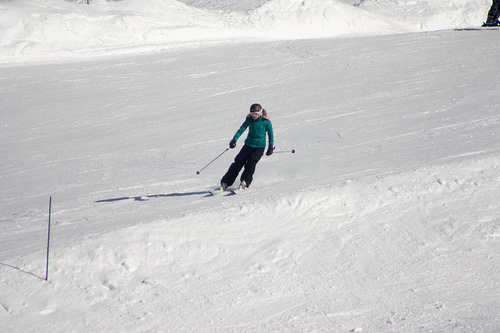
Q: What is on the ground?
A: Snow.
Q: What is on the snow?
A: Tracks.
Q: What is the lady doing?
A: Skiing.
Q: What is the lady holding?
A: Poles.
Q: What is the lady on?
A: Skis.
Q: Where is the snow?
A: On the hill.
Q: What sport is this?
A: Skiing.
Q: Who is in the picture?
A: A woman.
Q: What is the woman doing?
A: Skiing.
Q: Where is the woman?
A: At a ski slope.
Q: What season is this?
A: Winter.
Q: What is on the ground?
A: Snow.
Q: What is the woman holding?
A: Poles.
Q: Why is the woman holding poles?
A: Speed.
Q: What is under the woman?
A: Skis.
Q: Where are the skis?
A: On the woman's feet.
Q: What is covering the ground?
A: Snow.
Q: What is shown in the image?
A: A ski slope.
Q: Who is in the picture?
A: A skier.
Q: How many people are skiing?
A: One.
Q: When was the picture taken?
A: In winter.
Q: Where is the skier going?
A: Downhill.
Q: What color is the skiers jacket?
A: Green.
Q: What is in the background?
A: Snow hills.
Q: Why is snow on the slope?
A: It's cold.